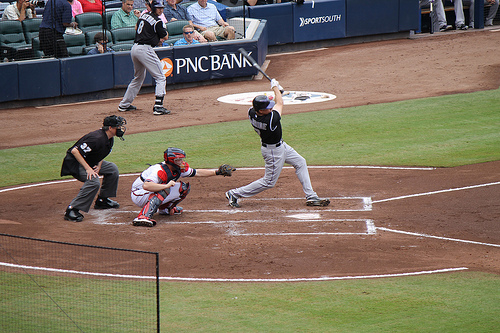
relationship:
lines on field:
[1, 175, 496, 292] [3, 31, 497, 331]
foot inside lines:
[207, 183, 378, 221] [209, 170, 383, 238]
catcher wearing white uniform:
[128, 144, 240, 232] [128, 165, 198, 214]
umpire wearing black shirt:
[56, 110, 133, 227] [59, 127, 118, 168]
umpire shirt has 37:
[56, 110, 133, 227] [76, 139, 94, 156]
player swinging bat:
[218, 43, 339, 212] [236, 41, 291, 95]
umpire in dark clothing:
[56, 110, 133, 227] [60, 127, 125, 212]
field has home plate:
[8, 66, 488, 333] [221, 188, 381, 245]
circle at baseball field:
[1, 175, 496, 292] [8, 66, 488, 333]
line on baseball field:
[370, 157, 499, 274] [8, 66, 488, 333]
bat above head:
[236, 41, 291, 95] [248, 92, 280, 116]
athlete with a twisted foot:
[218, 43, 339, 212] [297, 184, 337, 212]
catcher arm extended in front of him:
[128, 144, 240, 232] [183, 154, 239, 180]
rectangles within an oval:
[221, 188, 381, 245] [0, 161, 469, 289]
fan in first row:
[172, 19, 201, 47] [0, 36, 245, 53]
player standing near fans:
[113, 0, 182, 122] [167, 3, 237, 44]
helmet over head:
[248, 92, 276, 117] [248, 92, 280, 116]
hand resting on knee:
[71, 148, 104, 187] [81, 171, 107, 189]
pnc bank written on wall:
[173, 45, 263, 75] [160, 41, 265, 85]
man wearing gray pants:
[56, 110, 133, 227] [72, 156, 120, 208]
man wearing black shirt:
[56, 110, 133, 227] [59, 127, 118, 168]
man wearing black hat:
[56, 110, 133, 227] [100, 112, 128, 129]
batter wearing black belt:
[223, 75, 331, 210] [257, 139, 288, 148]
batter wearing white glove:
[223, 75, 331, 210] [267, 77, 285, 94]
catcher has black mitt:
[128, 144, 240, 232] [214, 160, 242, 180]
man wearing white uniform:
[128, 144, 240, 232] [128, 165, 198, 214]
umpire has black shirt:
[56, 110, 133, 227] [59, 127, 118, 168]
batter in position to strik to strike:
[218, 43, 339, 212] [226, 37, 296, 143]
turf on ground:
[1, 175, 496, 292] [8, 66, 488, 333]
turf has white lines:
[3, 151, 495, 292] [1, 175, 496, 292]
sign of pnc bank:
[160, 41, 265, 85] [173, 45, 263, 75]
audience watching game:
[3, 4, 241, 45] [8, 66, 488, 333]